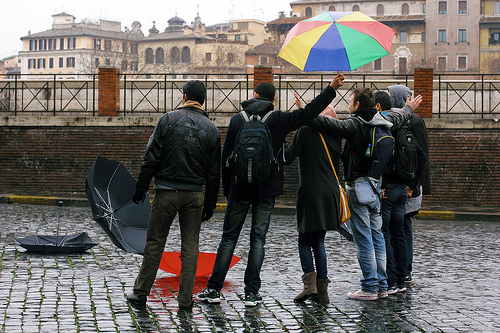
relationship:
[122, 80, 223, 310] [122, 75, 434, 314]
man in group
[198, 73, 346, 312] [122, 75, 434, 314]
man in group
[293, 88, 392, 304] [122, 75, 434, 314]
man in group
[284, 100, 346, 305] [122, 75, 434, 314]
woman in group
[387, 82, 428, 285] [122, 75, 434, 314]
man in group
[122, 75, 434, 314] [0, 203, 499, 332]
group on road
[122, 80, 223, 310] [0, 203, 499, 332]
man on road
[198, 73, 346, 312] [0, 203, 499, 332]
man on road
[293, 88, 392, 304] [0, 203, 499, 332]
man on road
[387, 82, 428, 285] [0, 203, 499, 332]
man on road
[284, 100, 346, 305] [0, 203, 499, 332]
woman on road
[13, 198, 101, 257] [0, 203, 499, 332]
umbrella on road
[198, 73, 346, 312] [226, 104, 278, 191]
man wears backpack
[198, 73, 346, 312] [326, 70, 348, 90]
man has hand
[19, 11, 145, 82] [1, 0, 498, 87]
building in distance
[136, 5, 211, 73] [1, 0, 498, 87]
building in distance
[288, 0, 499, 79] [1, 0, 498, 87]
building in distance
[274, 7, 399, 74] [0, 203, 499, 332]
umbrella on road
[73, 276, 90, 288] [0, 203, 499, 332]
cobblestone on road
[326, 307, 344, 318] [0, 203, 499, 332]
cobblestone on road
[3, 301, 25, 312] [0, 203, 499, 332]
cobblestone on road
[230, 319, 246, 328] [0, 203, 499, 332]
cobblestone on road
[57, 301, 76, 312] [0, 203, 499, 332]
cobblestone on road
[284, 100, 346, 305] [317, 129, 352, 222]
woman wears sling bag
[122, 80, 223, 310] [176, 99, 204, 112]
man wears scarf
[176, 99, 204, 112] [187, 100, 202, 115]
scarf around neck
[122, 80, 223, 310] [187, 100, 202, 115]
man has neck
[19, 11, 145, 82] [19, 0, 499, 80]
building in row of buildings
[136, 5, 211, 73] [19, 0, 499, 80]
building in row of buildings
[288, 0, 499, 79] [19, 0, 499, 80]
building in row of buildings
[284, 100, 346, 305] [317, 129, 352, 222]
woman has purse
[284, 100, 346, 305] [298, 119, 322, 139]
woman has shoulder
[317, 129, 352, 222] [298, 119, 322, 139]
purse on shoulder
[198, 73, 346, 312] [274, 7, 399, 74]
man holding umbrella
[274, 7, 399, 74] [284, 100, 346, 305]
umbrella above woman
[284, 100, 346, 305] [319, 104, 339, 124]
woman has head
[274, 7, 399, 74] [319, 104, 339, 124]
umbrella over head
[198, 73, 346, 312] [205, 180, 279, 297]
man wears jeans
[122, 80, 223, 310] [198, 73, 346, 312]
man next to man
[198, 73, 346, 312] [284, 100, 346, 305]
man next to woman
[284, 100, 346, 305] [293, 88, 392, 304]
woman next to man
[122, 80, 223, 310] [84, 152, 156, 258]
man holding umbrella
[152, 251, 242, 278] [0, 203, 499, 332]
umbrella on road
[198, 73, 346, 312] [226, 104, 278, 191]
man wearing backpack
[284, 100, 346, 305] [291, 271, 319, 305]
woman wears boot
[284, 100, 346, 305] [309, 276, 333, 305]
woman wears boot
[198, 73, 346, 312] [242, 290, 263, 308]
man wears shoe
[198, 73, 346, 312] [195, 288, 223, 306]
man wears shoe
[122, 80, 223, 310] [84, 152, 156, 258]
man holds umbrella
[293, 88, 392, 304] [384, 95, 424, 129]
man has arm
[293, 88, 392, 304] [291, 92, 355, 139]
man has arm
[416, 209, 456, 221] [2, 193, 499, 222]
paint on curb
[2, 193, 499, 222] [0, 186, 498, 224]
curb on sidewalk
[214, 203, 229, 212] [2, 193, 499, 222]
paint on curb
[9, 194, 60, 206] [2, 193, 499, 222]
paint on curb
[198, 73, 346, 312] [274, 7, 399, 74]
man holds umbrella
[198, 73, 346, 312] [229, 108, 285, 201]
man has back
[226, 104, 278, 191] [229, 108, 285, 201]
backpack on back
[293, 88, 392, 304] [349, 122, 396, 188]
man wears backpack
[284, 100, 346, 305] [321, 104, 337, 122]
woman wears hat